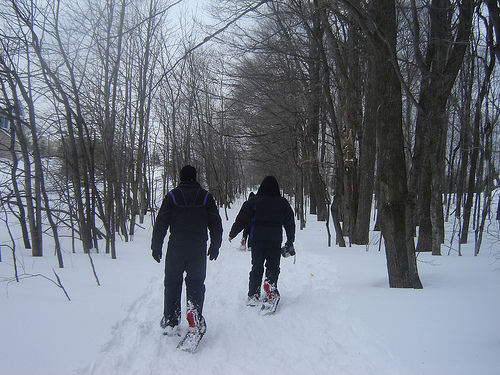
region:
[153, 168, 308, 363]
people walking in the snow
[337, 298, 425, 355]
the snow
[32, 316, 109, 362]
the snow is white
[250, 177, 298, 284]
a person walking in the snow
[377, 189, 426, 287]
a tree trunk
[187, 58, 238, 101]
tree branches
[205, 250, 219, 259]
person wearing a glove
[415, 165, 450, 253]
the bark on the tree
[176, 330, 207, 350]
a ski in the snow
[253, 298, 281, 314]
the ski has snow on it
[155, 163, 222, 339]
a man is walking on the snow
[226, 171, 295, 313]
a man is walking on the snow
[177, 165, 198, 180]
the man is wearing a hat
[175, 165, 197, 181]
the hat is black in color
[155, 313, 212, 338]
the man is stepping on snow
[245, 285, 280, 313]
the man is stepping on snow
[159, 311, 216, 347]
the man has snow on his boots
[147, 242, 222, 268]
the man is wearing gloves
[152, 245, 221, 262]
the gloves are black in color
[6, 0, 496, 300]
the trees are bare of branches